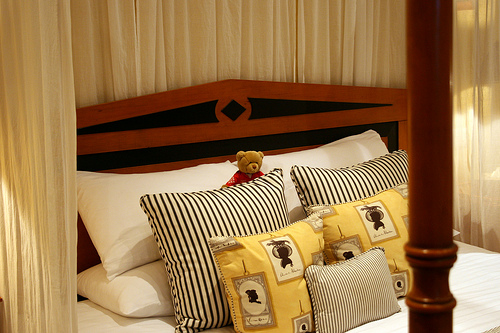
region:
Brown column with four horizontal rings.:
[403, 0, 456, 330]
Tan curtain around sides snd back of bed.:
[0, 0, 499, 329]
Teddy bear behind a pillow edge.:
[223, 151, 270, 184]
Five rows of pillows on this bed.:
[78, 124, 407, 327]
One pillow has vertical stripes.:
[302, 247, 407, 331]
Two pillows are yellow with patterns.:
[207, 177, 418, 330]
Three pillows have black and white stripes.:
[138, 150, 412, 326]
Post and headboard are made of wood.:
[63, 82, 458, 269]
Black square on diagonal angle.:
[221, 97, 248, 124]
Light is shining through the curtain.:
[453, 0, 498, 247]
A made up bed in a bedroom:
[6, 13, 493, 321]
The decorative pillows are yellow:
[210, 195, 410, 271]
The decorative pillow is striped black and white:
[153, 200, 225, 329]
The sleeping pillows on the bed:
[86, 178, 171, 320]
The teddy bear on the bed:
[223, 136, 265, 193]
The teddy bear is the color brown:
[221, 145, 268, 192]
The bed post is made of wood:
[400, 10, 483, 330]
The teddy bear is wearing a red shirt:
[220, 170, 275, 190]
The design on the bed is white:
[101, 95, 349, 137]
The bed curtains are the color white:
[28, 2, 409, 79]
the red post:
[405, 2, 455, 329]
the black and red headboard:
[75, 75, 405, 262]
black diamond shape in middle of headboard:
[220, 95, 245, 122]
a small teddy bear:
[220, 147, 261, 187]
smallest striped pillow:
[302, 245, 394, 330]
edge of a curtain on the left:
[0, 0, 71, 330]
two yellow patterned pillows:
[207, 182, 417, 327]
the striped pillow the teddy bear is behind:
[137, 167, 283, 327]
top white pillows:
[75, 130, 382, 275]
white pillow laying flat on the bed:
[78, 261, 173, 317]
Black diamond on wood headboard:
[207, 92, 259, 127]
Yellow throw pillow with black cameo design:
[230, 234, 301, 326]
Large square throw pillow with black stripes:
[167, 189, 269, 237]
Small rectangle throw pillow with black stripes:
[317, 258, 381, 330]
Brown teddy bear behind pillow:
[225, 145, 271, 186]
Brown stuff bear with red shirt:
[228, 148, 263, 188]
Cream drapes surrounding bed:
[17, 20, 69, 331]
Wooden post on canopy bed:
[415, 14, 449, 323]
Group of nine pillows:
[104, 138, 392, 318]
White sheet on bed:
[459, 253, 494, 329]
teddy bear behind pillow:
[196, 137, 278, 197]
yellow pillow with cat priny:
[226, 223, 311, 309]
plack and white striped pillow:
[151, 155, 290, 288]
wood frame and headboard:
[119, 81, 452, 301]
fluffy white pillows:
[87, 167, 195, 309]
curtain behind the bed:
[29, 20, 349, 135]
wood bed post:
[395, 13, 440, 332]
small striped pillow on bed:
[309, 250, 414, 325]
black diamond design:
[206, 93, 273, 135]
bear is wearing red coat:
[224, 167, 264, 192]